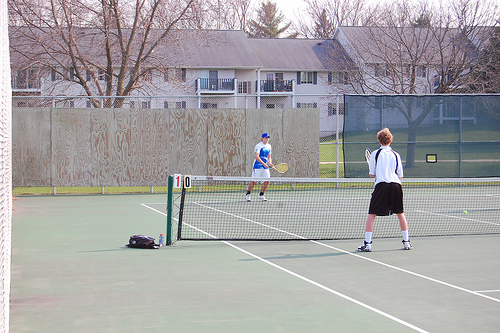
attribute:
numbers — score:
[172, 171, 192, 190]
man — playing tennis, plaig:
[355, 126, 414, 251]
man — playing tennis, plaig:
[243, 131, 289, 201]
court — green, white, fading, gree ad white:
[11, 185, 498, 331]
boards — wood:
[13, 106, 319, 188]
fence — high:
[13, 94, 499, 197]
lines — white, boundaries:
[141, 192, 498, 332]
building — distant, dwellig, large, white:
[7, 24, 499, 140]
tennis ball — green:
[461, 209, 468, 216]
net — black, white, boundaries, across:
[162, 172, 498, 244]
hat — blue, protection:
[260, 130, 270, 138]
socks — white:
[363, 227, 408, 241]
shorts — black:
[367, 179, 405, 217]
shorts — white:
[250, 167, 272, 184]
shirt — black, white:
[367, 143, 403, 185]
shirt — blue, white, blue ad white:
[251, 142, 273, 170]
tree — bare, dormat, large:
[8, 0, 224, 108]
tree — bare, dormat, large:
[293, 0, 498, 170]